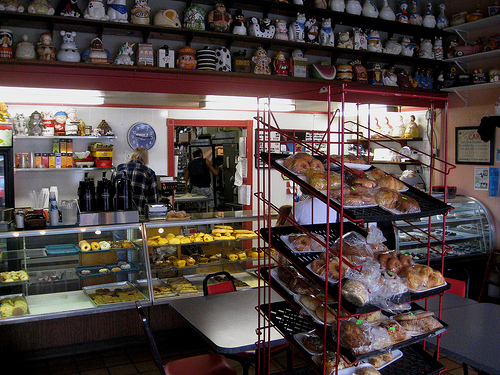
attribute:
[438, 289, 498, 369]
tables — silver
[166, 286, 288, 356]
tables — silver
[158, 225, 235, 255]
cookie — different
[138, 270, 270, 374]
chair — red, black, metal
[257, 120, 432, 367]
tray holder — red, metal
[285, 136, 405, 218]
bagels — light brown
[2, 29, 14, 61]
package — quaker oats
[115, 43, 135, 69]
jar — white, unicorn shaped, cookie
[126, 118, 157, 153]
wall clock — blue, silver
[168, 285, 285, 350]
table — gray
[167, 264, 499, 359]
table — silver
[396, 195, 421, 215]
pastries — assorted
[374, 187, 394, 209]
pastries — assorted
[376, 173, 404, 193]
pastries — assorted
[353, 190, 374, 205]
pastries — assorted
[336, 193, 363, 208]
pastries — assorted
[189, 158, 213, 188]
shirt — black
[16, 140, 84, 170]
tea boxes — multi colored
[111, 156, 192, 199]
shirt — plaid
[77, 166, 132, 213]
coffee dispensers — three, black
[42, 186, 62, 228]
cups — drinking, white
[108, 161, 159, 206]
shirt — checker pattern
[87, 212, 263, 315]
donuts — a row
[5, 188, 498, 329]
display case — bakery's glass, glass, oval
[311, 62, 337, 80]
cookie jar — watermelon shaped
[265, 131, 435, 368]
cart — red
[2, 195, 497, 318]
counter — bakery